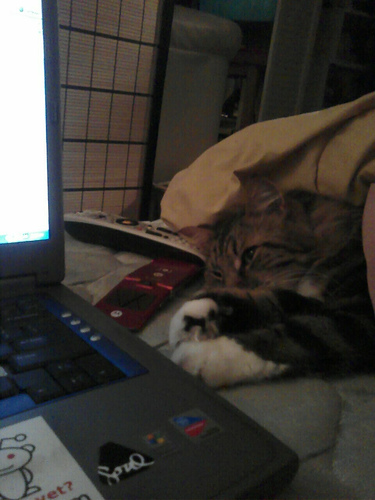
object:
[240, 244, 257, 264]
eye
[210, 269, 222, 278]
eye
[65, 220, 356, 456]
matress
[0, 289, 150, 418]
keyboard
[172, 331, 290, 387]
paw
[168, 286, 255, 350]
paw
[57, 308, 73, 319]
button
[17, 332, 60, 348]
button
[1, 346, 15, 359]
button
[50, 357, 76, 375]
button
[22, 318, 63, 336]
button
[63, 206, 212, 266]
remote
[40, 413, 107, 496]
sticker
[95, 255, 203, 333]
cell phone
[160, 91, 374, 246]
blanket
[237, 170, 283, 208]
ears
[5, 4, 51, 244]
screen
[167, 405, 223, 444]
sticker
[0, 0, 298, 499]
computer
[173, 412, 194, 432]
intel logo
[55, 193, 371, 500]
bed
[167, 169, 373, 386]
cat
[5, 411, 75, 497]
logo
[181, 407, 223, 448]
logo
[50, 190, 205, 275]
control